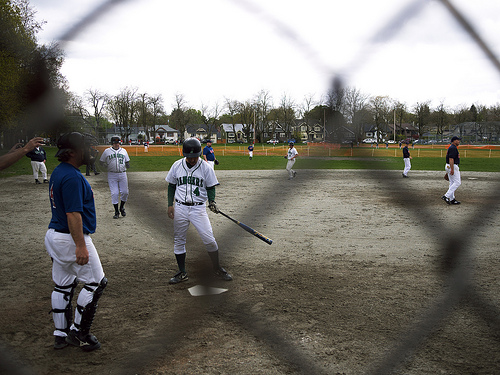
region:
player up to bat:
[152, 133, 274, 305]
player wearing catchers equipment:
[37, 120, 117, 357]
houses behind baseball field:
[98, 118, 467, 155]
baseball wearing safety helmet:
[168, 130, 209, 174]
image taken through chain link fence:
[8, 6, 475, 361]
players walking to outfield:
[379, 128, 473, 210]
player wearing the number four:
[183, 175, 211, 212]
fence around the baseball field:
[108, 129, 487, 170]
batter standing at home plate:
[175, 273, 241, 308]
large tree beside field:
[6, 5, 78, 177]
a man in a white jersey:
[161, 131, 239, 290]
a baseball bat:
[204, 198, 281, 255]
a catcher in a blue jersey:
[36, 118, 113, 360]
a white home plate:
[167, 268, 247, 318]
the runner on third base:
[87, 120, 149, 235]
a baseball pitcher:
[432, 129, 476, 218]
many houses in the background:
[57, 115, 499, 152]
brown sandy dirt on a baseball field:
[132, 176, 483, 361]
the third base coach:
[14, 128, 60, 190]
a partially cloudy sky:
[91, 4, 496, 116]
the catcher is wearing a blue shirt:
[46, 155, 102, 240]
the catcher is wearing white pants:
[36, 220, 113, 341]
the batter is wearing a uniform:
[159, 154, 224, 257]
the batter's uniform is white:
[161, 155, 228, 258]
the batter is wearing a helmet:
[178, 135, 205, 160]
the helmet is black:
[181, 137, 201, 157]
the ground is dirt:
[0, 165, 499, 372]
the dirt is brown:
[2, 166, 499, 373]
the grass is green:
[3, 137, 498, 174]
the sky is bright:
[1, 0, 498, 160]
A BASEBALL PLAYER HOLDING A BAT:
[158, 133, 280, 285]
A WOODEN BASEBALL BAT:
[202, 195, 280, 251]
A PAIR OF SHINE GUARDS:
[42, 276, 132, 353]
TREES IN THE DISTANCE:
[80, 80, 172, 144]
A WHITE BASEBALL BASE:
[177, 280, 244, 301]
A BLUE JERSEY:
[36, 162, 111, 243]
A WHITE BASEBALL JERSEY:
[163, 158, 227, 205]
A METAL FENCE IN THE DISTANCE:
[302, 138, 415, 161]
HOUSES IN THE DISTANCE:
[210, 109, 337, 148]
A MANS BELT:
[170, 194, 227, 211]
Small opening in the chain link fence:
[198, 123, 455, 373]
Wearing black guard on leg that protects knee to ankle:
[82, 279, 109, 329]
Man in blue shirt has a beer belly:
[84, 202, 102, 235]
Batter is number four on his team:
[173, 157, 214, 209]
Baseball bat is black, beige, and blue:
[212, 204, 279, 246]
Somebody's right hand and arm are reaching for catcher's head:
[2, 132, 49, 167]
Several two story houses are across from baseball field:
[220, 120, 354, 145]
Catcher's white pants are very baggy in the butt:
[36, 227, 80, 268]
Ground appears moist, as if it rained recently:
[262, 255, 487, 363]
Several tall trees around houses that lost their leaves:
[223, 92, 367, 107]